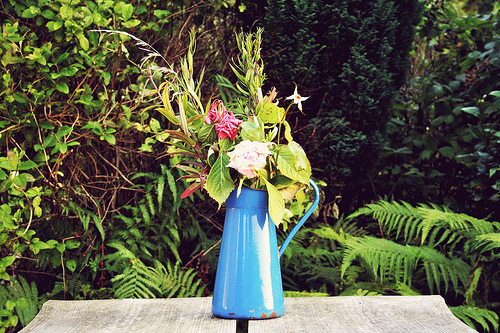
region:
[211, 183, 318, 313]
blue watering can with handle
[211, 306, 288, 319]
rust spots or paint chipped from the bottom of can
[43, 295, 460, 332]
two separate tables are holding up the can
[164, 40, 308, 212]
strategically arranged flowers in can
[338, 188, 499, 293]
wild ferns growing in the background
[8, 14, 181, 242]
wild bush with wild twigs growing in the back to the left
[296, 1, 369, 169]
hedge growing even further back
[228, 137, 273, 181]
one rose-like flower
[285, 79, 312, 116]
one flower with four visible petals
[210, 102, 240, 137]
one deep red flower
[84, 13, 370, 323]
blue pitcher holding flowers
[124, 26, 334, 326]
antique pitcher used as a vase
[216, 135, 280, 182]
pink flower surrounded by greenery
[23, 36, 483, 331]
blue pitcher with flowers on a table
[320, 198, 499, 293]
palm fronds in the distance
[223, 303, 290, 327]
rust spots on a blue pitcher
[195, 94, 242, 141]
magenta flower surrounded by greenery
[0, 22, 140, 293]
trees and vines outdoors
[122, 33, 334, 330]
rusty vase with flowers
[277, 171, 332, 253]
blue handle on a pitcher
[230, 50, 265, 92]
part of a plant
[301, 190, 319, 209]
part of a handle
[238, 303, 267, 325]
edge of a base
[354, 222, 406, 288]
part of a plant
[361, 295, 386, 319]
part of a floor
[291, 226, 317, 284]
part of a handke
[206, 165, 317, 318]
a blue watering can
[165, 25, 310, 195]
a bunch of wilted flowers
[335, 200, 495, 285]
green fern plant; left side image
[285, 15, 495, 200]
bushes fill the background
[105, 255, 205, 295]
green fern plant near blue can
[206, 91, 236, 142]
a pink flower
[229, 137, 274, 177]
a light pink flower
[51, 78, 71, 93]
leaves of the bush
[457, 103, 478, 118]
leaves of the bush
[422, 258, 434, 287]
fern has long leaves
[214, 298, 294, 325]
rust spots on a vase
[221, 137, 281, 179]
large pink peony with greens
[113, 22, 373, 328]
blue pitcher on a table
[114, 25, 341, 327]
blue metal pitcher used as vase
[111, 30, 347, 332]
still life with pitcher and flowers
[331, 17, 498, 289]
foliage in a garden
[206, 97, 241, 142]
hot pink flower surrounded by greens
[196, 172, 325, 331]
blue antique pitcher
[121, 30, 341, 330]
pretty blue vase